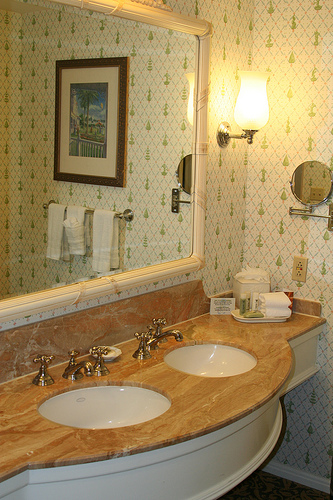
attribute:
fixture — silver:
[32, 353, 54, 388]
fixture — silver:
[60, 346, 94, 383]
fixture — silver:
[88, 345, 110, 379]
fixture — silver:
[131, 330, 156, 361]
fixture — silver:
[146, 318, 181, 346]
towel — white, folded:
[257, 290, 292, 307]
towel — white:
[259, 304, 292, 319]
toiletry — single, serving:
[239, 293, 245, 315]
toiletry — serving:
[244, 290, 249, 314]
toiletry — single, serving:
[251, 291, 258, 309]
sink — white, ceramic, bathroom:
[165, 339, 260, 379]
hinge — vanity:
[287, 203, 319, 218]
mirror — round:
[285, 158, 331, 223]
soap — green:
[240, 310, 262, 321]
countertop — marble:
[0, 310, 329, 480]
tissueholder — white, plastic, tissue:
[231, 276, 270, 304]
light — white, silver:
[206, 63, 278, 159]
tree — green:
[287, 51, 296, 65]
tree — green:
[284, 90, 292, 100]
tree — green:
[280, 155, 290, 166]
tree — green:
[280, 191, 288, 201]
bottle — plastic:
[239, 294, 246, 315]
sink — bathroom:
[29, 356, 195, 462]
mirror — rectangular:
[0, 19, 232, 289]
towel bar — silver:
[42, 199, 134, 220]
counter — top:
[1, 300, 325, 483]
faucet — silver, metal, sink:
[145, 318, 186, 346]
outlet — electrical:
[288, 252, 311, 285]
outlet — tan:
[288, 253, 307, 282]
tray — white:
[230, 306, 291, 322]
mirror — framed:
[2, 2, 217, 314]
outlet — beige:
[289, 254, 308, 284]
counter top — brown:
[0, 306, 332, 490]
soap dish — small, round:
[86, 342, 122, 362]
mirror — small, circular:
[287, 151, 331, 211]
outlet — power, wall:
[291, 251, 319, 280]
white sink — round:
[145, 328, 271, 389]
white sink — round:
[37, 368, 183, 437]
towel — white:
[44, 202, 69, 261]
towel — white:
[59, 205, 88, 256]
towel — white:
[89, 208, 119, 273]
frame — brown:
[51, 54, 130, 185]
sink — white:
[38, 382, 172, 429]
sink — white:
[163, 339, 257, 376]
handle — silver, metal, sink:
[131, 330, 153, 360]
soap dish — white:
[87, 344, 122, 362]